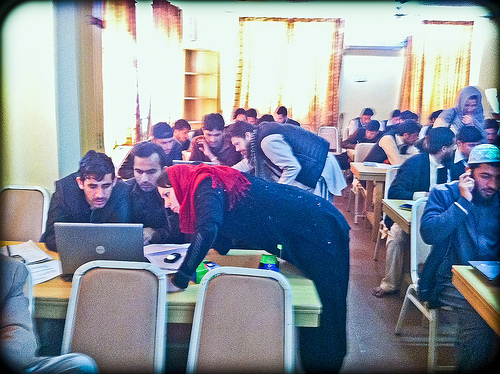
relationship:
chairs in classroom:
[70, 256, 323, 364] [2, 3, 497, 372]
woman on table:
[154, 160, 342, 275] [15, 294, 316, 325]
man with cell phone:
[426, 146, 491, 254] [455, 161, 474, 187]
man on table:
[244, 122, 342, 194] [132, 174, 306, 186]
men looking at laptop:
[69, 149, 164, 213] [50, 216, 145, 257]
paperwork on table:
[15, 237, 46, 270] [15, 294, 316, 325]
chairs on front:
[70, 256, 323, 364] [9, 254, 498, 367]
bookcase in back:
[173, 42, 224, 119] [72, 0, 459, 108]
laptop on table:
[50, 216, 145, 257] [15, 294, 316, 325]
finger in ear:
[458, 170, 474, 193] [462, 158, 469, 177]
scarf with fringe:
[162, 161, 231, 222] [226, 181, 252, 200]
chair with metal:
[191, 266, 295, 369] [231, 263, 275, 281]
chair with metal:
[74, 259, 169, 370] [113, 257, 138, 270]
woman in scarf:
[154, 160, 342, 275] [162, 161, 231, 222]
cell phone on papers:
[164, 247, 177, 266] [153, 236, 185, 269]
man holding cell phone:
[426, 146, 491, 254] [455, 161, 474, 187]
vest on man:
[255, 121, 329, 190] [244, 122, 342, 194]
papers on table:
[153, 236, 185, 269] [15, 294, 316, 325]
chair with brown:
[191, 266, 295, 369] [225, 302, 253, 360]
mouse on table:
[164, 245, 179, 264] [15, 294, 316, 325]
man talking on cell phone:
[426, 146, 491, 254] [455, 161, 474, 187]